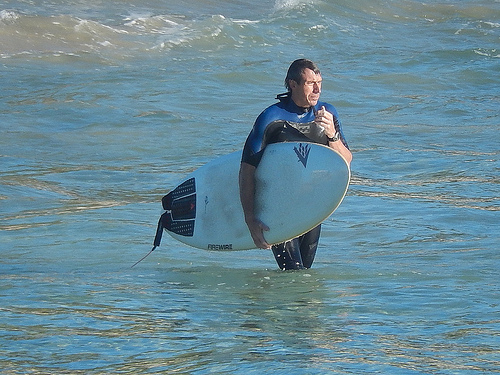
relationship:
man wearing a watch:
[257, 60, 340, 270] [326, 131, 342, 141]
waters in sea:
[1, 1, 499, 372] [3, 0, 499, 374]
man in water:
[237, 58, 354, 270] [0, 0, 497, 373]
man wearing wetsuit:
[237, 58, 354, 270] [239, 100, 351, 271]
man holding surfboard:
[237, 58, 354, 270] [149, 137, 349, 255]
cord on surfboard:
[122, 221, 167, 271] [149, 137, 349, 255]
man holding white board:
[237, 58, 354, 270] [154, 142, 349, 253]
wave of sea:
[0, 0, 500, 61] [0, 0, 499, 374]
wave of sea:
[118, 7, 195, 39] [0, 0, 499, 374]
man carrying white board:
[237, 58, 354, 270] [159, 142, 350, 252]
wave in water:
[0, 0, 500, 61] [0, 0, 497, 373]